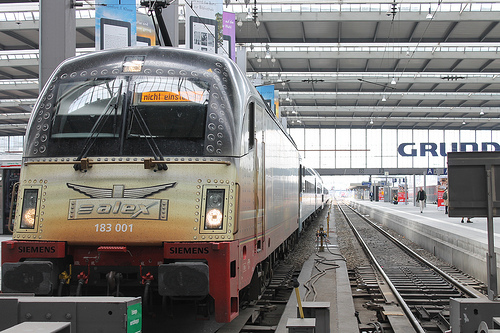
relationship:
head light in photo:
[194, 183, 228, 237] [8, 15, 476, 326]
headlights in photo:
[17, 185, 40, 232] [8, 15, 476, 326]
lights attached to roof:
[314, 46, 474, 137] [308, 2, 463, 135]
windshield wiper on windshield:
[129, 106, 168, 171] [75, 60, 217, 111]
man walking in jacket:
[415, 185, 426, 212] [413, 190, 426, 200]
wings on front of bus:
[66, 181, 175, 200] [5, 45, 329, 321]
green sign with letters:
[135, 302, 145, 332] [128, 303, 140, 328]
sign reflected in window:
[128, 70, 220, 117] [22, 48, 239, 154]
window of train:
[22, 48, 239, 154] [54, 59, 259, 247]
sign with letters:
[128, 70, 220, 117] [140, 92, 189, 101]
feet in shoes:
[456, 212, 475, 227] [459, 218, 474, 225]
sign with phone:
[93, 4, 136, 47] [100, 20, 127, 48]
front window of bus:
[24, 52, 236, 156] [5, 45, 330, 328]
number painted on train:
[94, 223, 133, 233] [59, 12, 331, 307]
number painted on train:
[110, 223, 136, 233] [59, 12, 331, 307]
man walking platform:
[415, 186, 426, 212] [337, 190, 494, 250]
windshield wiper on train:
[126, 97, 166, 170] [45, 40, 332, 299]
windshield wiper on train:
[74, 93, 120, 170] [45, 40, 332, 299]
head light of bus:
[194, 183, 228, 237] [5, 45, 330, 328]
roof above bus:
[0, 3, 495, 133] [5, 45, 330, 328]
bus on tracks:
[5, 45, 330, 328] [253, 196, 494, 331]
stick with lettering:
[126, 303, 143, 330] [128, 304, 140, 329]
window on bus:
[43, 73, 210, 157] [5, 45, 330, 328]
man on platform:
[415, 186, 426, 212] [343, 155, 499, 270]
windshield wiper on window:
[129, 106, 168, 171] [51, 75, 208, 155]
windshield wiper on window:
[74, 92, 121, 161] [51, 75, 208, 155]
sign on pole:
[452, 149, 497, 211] [489, 167, 497, 292]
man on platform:
[415, 186, 426, 212] [335, 170, 497, 298]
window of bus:
[43, 73, 210, 157] [5, 45, 330, 328]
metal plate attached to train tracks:
[448, 148, 499, 328] [327, 155, 460, 319]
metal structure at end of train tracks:
[1, 294, 146, 331] [259, 196, 498, 331]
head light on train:
[194, 183, 228, 237] [21, 45, 383, 320]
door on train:
[250, 105, 269, 254] [29, 56, 330, 319]